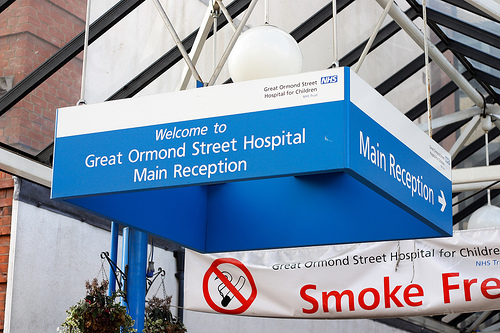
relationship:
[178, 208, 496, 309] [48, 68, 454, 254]
banner behind box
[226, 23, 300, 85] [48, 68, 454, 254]
globe hangs above box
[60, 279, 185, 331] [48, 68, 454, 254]
baskets hang below box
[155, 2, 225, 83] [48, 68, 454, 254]
framework above box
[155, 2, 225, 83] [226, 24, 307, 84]
framework above light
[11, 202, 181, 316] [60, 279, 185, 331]
tarp behind baskets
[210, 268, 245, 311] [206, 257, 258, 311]
cigarette with cross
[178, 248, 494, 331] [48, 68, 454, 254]
wall behind box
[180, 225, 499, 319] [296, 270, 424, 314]
banner with word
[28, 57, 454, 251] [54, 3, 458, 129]
box attached to poles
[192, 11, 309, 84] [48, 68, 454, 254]
globe above box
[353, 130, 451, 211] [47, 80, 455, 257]
direction are attached to sign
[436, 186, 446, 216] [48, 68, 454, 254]
arrow attached to box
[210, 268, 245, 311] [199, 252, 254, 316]
cigarette inside of circle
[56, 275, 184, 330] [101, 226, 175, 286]
bushes hanging from a pole